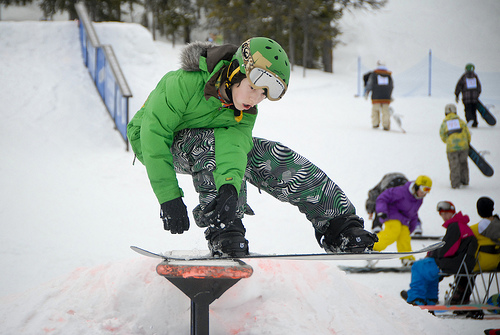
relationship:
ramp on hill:
[71, 0, 132, 148] [0, 21, 184, 261]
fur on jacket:
[177, 36, 217, 72] [437, 114, 474, 157]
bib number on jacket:
[446, 118, 463, 134] [437, 114, 474, 157]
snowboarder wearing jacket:
[121, 35, 381, 255] [119, 56, 264, 203]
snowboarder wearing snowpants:
[371, 175, 435, 269] [370, 219, 416, 263]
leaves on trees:
[250, 1, 335, 35] [1, 1, 388, 74]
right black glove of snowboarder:
[157, 194, 192, 238] [121, 35, 381, 255]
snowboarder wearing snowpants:
[364, 57, 399, 132] [371, 101, 395, 132]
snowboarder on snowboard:
[121, 35, 381, 255] [126, 238, 450, 266]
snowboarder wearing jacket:
[371, 175, 435, 269] [368, 184, 424, 233]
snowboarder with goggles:
[121, 35, 381, 255] [237, 39, 287, 101]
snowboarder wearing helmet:
[121, 35, 381, 255] [228, 37, 294, 101]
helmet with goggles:
[228, 37, 294, 101] [237, 39, 287, 101]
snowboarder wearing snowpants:
[437, 101, 471, 190] [446, 148, 472, 187]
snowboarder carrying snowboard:
[437, 101, 471, 190] [461, 143, 499, 177]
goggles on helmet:
[237, 39, 287, 101] [228, 37, 294, 101]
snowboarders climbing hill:
[363, 50, 497, 197] [354, 52, 497, 189]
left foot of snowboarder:
[318, 211, 379, 252] [121, 35, 381, 255]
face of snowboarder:
[232, 75, 270, 114] [121, 35, 381, 255]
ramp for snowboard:
[71, 0, 132, 148] [126, 238, 450, 266]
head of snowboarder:
[216, 34, 294, 116] [121, 35, 381, 255]